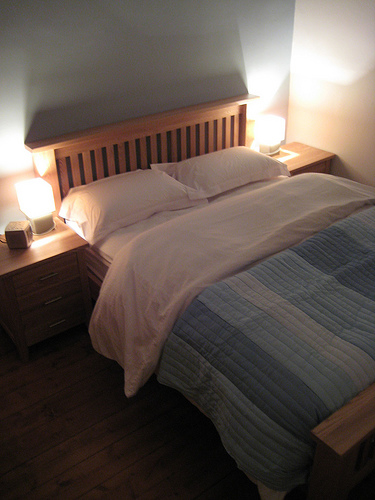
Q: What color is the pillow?
A: White.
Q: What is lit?
A: The room.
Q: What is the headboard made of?
A: Wood.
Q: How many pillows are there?
A: Two.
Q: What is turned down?
A: White comforter.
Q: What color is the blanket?
A: Blue and white striped.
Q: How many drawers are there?
A: Three.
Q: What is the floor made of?
A: Wood.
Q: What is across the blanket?
A: Fold line.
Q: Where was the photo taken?
A: In a room.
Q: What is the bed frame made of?
A: Wood.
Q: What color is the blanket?
A: Blue.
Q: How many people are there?
A: None.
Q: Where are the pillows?
A: On the bed.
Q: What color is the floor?
A: Brown.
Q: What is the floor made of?
A: Wood.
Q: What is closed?
A: The drawer.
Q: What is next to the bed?
A: Lamps.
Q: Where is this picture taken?
A: A bedroom.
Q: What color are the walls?
A: Grey and white.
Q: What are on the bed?
A: Pillows.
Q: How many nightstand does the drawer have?
A: Three.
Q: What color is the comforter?
A: Blue.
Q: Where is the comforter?
A: On bed.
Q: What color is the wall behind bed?
A: Light blue.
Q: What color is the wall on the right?
A: White.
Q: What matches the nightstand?
A: Headboard.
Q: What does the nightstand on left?
A: Drawer.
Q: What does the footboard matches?
A: Headboard.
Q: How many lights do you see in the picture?
A: Two.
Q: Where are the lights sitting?
A: On the night tables.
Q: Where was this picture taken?
A: In the bedroom.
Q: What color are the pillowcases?
A: White.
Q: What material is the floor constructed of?
A: Wood.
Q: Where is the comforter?
A: On the bed.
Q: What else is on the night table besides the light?
A: A clock.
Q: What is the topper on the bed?
A: A comforter.